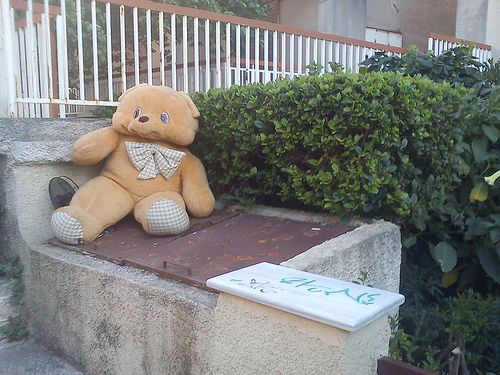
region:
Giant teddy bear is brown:
[89, 78, 212, 239]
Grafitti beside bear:
[266, 252, 396, 349]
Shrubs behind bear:
[205, 76, 445, 204]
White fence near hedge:
[23, 4, 300, 96]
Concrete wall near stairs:
[36, 255, 199, 362]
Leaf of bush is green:
[436, 234, 456, 274]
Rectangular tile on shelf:
[251, 245, 389, 332]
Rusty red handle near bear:
[161, 248, 195, 274]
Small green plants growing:
[2, 240, 31, 345]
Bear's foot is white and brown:
[53, 211, 91, 240]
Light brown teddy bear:
[45, 67, 231, 268]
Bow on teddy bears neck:
[116, 135, 187, 182]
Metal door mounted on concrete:
[116, 207, 393, 273]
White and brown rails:
[172, 5, 357, 70]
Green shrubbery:
[228, 61, 461, 213]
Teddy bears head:
[108, 80, 200, 146]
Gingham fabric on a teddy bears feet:
[48, 193, 193, 246]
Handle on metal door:
[150, 255, 195, 286]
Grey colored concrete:
[45, 291, 136, 356]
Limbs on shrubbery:
[441, 344, 477, 374]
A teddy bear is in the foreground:
[34, 76, 230, 249]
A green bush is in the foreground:
[216, 66, 468, 214]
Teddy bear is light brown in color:
[46, 73, 226, 266]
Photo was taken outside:
[7, 6, 490, 370]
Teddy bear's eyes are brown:
[127, 103, 181, 128]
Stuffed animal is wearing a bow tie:
[119, 133, 192, 190]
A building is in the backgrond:
[284, 1, 499, 71]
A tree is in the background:
[68, 3, 278, 89]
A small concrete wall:
[11, 278, 202, 373]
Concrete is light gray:
[1, 296, 216, 373]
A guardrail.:
[146, 1, 403, 81]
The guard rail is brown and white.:
[151, 1, 372, 94]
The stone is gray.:
[50, 297, 194, 372]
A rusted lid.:
[138, 209, 345, 302]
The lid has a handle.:
[151, 255, 200, 290]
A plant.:
[225, 77, 495, 208]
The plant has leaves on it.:
[255, 76, 497, 200]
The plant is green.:
[258, 74, 496, 219]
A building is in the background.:
[222, 0, 498, 124]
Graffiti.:
[227, 259, 414, 338]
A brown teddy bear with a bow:
[38, 57, 223, 258]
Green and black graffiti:
[206, 253, 387, 333]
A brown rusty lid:
[115, 200, 366, 305]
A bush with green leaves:
[205, 63, 456, 198]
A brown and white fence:
[46, 0, 364, 83]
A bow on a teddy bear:
[120, 130, 195, 180]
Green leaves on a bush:
[441, 109, 499, 284]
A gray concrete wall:
[43, 257, 179, 364]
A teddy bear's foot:
[133, 187, 190, 241]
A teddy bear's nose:
[136, 110, 156, 129]